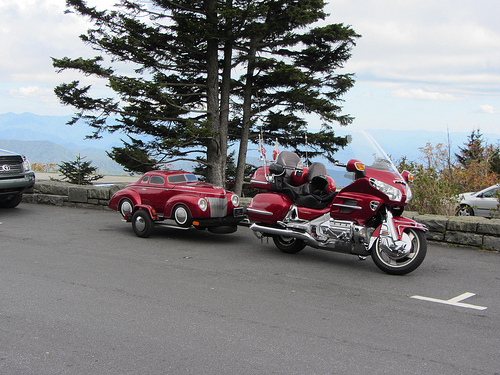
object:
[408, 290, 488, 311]
white mark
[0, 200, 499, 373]
paved street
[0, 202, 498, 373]
black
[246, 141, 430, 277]
bike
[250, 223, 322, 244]
silencer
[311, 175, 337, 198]
helmet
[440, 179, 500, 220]
car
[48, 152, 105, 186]
tree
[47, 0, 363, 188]
tree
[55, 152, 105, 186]
bush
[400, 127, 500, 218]
trees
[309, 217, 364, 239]
engine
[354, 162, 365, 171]
indicator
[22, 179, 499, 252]
fence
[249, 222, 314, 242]
exhaust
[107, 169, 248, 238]
car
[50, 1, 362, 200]
tree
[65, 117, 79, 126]
leaf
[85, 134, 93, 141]
leaf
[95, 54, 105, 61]
leaf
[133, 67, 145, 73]
leaf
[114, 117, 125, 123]
leaf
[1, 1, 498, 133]
clouds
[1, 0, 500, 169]
sky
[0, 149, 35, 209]
front end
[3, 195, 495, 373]
road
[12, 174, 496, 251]
wall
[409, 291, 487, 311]
lines